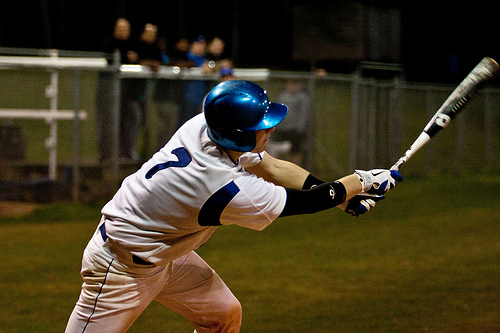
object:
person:
[271, 78, 312, 168]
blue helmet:
[202, 77, 290, 154]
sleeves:
[278, 181, 346, 219]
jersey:
[98, 114, 292, 271]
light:
[234, 92, 256, 106]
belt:
[98, 222, 191, 260]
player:
[56, 46, 406, 331]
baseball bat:
[342, 56, 500, 218]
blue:
[195, 177, 238, 234]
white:
[134, 191, 187, 229]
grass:
[377, 219, 483, 295]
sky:
[232, 17, 281, 57]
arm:
[233, 151, 325, 178]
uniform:
[58, 112, 287, 333]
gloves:
[346, 195, 379, 217]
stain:
[188, 300, 244, 333]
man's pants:
[63, 228, 242, 333]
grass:
[295, 283, 367, 325]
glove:
[353, 167, 403, 197]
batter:
[65, 55, 499, 333]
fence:
[0, 52, 500, 196]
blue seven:
[146, 146, 191, 180]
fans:
[108, 8, 240, 154]